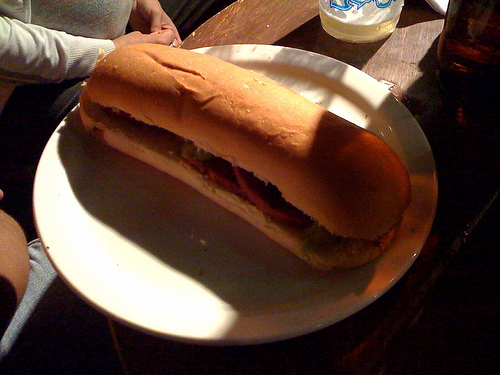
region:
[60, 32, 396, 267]
hot dog on the plate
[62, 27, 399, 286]
sandwich on a plate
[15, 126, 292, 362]
plate under a sandwich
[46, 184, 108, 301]
light casted on the plate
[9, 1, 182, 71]
arms of a man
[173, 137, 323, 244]
tomatoes in a sandwich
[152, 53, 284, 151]
bread on a sandwich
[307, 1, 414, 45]
cake on a table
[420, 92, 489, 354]
shadow on the table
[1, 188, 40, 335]
elbow of a man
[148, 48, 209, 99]
crease in the bread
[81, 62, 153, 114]
bun on a plate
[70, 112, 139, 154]
bun on a plate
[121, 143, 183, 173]
bun on a plate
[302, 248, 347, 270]
bun on a plate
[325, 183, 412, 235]
bun on a plate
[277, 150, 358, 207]
bun on a plate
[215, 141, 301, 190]
bun on a plate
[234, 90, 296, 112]
bun on a plate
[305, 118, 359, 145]
bun on a plate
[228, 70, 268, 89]
bun on a plate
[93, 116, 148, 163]
bun on a plate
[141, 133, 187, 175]
bun on a plate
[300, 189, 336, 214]
bun on a plate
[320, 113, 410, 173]
bun on a plate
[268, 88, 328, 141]
bun on a plate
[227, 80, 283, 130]
bun on a plate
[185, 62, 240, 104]
bun on a plate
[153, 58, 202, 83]
bun on a plate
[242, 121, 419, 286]
The front portion of a hot dog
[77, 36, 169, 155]
The back portion of a hot dog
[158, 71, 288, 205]
The middle portion of a hot dog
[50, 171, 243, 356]
The bottom left portion of a white plate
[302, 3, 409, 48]
The bottom portion of a cup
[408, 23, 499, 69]
The bottom portion of a brown glass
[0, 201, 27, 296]
the edge of a brown object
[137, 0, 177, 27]
Part of a person's left hand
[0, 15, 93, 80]
Part of a person's right sleeve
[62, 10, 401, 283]
A hot dog